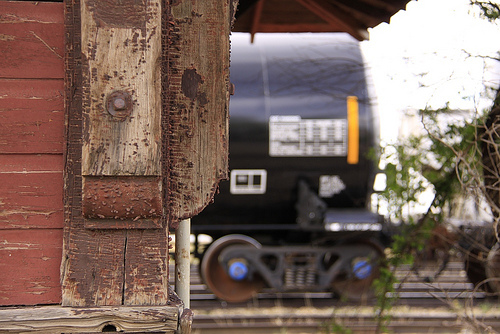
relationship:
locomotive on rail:
[161, 32, 420, 314] [171, 233, 427, 332]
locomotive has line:
[161, 32, 420, 314] [343, 95, 361, 165]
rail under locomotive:
[171, 233, 427, 332] [161, 32, 420, 314]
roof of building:
[273, 9, 363, 29] [3, 8, 419, 263]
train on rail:
[146, 18, 440, 297] [171, 233, 500, 332]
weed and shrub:
[394, 147, 460, 230] [391, 141, 497, 243]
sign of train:
[224, 158, 283, 201] [146, 18, 440, 297]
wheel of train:
[187, 214, 295, 310] [146, 18, 440, 297]